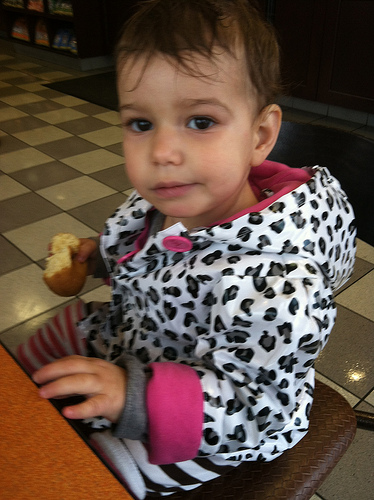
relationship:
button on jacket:
[162, 235, 193, 253] [68, 158, 363, 471]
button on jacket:
[116, 247, 140, 264] [68, 158, 363, 471]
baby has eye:
[16, 0, 357, 499] [124, 118, 154, 134]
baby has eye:
[16, 0, 357, 499] [184, 111, 220, 132]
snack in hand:
[34, 230, 111, 312] [72, 233, 103, 285]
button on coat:
[116, 243, 142, 264] [72, 157, 359, 464]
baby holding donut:
[11, 1, 356, 495] [43, 231, 90, 296]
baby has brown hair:
[16, 0, 357, 499] [112, 0, 285, 109]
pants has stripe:
[13, 297, 244, 499] [154, 456, 198, 485]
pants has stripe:
[13, 297, 244, 499] [59, 305, 84, 353]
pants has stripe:
[13, 297, 244, 499] [26, 334, 57, 369]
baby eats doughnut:
[16, 0, 357, 499] [39, 228, 92, 301]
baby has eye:
[16, 0, 357, 499] [185, 114, 216, 133]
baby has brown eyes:
[16, 0, 357, 499] [123, 116, 152, 137]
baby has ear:
[16, 0, 357, 499] [252, 103, 281, 166]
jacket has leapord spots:
[68, 158, 363, 471] [145, 238, 318, 413]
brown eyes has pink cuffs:
[123, 116, 152, 137] [150, 361, 197, 459]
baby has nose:
[16, 0, 357, 499] [150, 132, 190, 170]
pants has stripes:
[6, 297, 109, 374] [21, 316, 68, 347]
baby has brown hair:
[16, 0, 357, 499] [119, 5, 296, 96]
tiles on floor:
[2, 61, 373, 418] [2, 37, 371, 437]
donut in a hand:
[43, 231, 90, 296] [75, 237, 95, 263]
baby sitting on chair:
[16, 0, 357, 499] [171, 377, 372, 498]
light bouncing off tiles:
[9, 295, 47, 324] [1, 131, 51, 327]